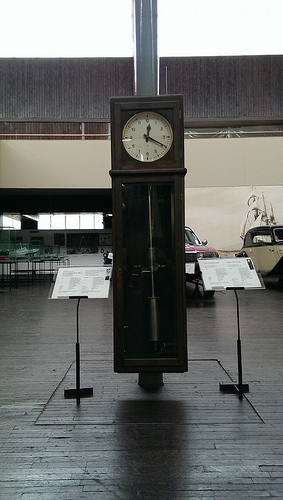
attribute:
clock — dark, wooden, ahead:
[106, 88, 187, 377]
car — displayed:
[242, 225, 282, 285]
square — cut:
[40, 355, 267, 434]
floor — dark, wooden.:
[0, 272, 282, 499]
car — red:
[103, 225, 221, 274]